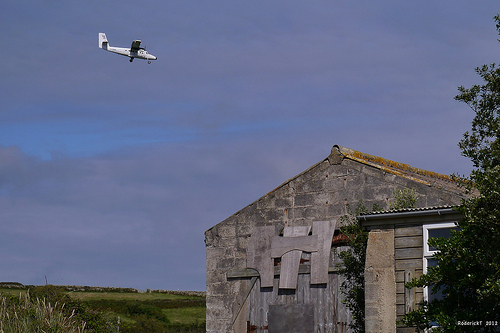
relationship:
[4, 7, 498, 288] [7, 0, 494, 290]
clouds in sky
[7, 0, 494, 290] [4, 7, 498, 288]
sky with clouds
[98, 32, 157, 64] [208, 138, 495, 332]
aeroplane flying over a building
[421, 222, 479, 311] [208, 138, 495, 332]
window in a building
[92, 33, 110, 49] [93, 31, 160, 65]
tail of a plane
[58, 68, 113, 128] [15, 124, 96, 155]
clouds in sky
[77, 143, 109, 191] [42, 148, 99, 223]
clouds in sky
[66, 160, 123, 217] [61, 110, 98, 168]
clouds in sky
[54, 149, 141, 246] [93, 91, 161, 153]
clouds in sky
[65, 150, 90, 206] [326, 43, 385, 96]
clouds in sky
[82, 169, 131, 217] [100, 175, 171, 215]
clouds in sky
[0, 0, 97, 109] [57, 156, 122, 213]
clouds in sky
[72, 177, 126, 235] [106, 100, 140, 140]
clouds in sky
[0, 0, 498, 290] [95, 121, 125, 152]
sky in clouds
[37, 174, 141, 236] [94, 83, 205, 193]
clouds in sky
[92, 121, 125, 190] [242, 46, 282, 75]
clouds in sky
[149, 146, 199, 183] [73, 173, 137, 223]
clouds in sky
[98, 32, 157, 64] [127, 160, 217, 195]
aeroplane in air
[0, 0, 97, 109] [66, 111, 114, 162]
clouds in sky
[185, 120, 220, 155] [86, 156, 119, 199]
clouds in sky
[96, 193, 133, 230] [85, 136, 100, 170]
clouds in sky